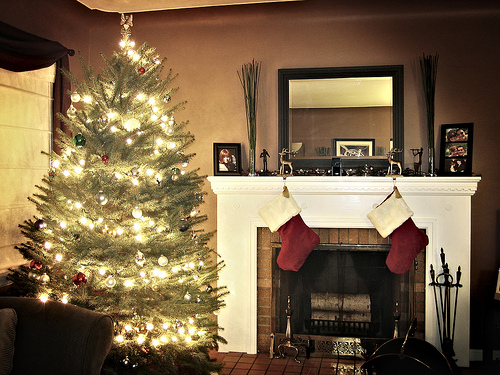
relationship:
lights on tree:
[136, 96, 186, 151] [9, 22, 219, 371]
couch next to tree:
[13, 291, 120, 365] [58, 22, 247, 372]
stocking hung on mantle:
[368, 185, 429, 273] [206, 173, 480, 195]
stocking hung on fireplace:
[258, 189, 320, 272] [260, 226, 493, 355]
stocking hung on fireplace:
[366, 185, 428, 275] [260, 226, 493, 355]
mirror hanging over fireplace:
[280, 72, 400, 160] [260, 217, 427, 344]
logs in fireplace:
[311, 292, 372, 328] [192, 153, 494, 371]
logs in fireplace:
[296, 295, 383, 328] [227, 158, 448, 348]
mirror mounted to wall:
[287, 75, 396, 161] [171, 33, 241, 104]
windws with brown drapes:
[5, 68, 99, 290] [3, 41, 94, 128]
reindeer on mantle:
[276, 150, 297, 173] [202, 140, 494, 196]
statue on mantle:
[255, 145, 272, 175] [205, 171, 483, 201]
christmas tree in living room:
[0, 7, 237, 373] [10, 10, 490, 339]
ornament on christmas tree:
[62, 267, 88, 287] [6, 7, 230, 375]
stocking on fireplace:
[255, 190, 325, 268] [206, 170, 481, 367]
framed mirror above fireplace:
[267, 58, 409, 173] [203, 166, 497, 374]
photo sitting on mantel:
[205, 135, 250, 177] [203, 169, 487, 198]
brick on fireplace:
[212, 349, 338, 374] [257, 226, 424, 359]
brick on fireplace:
[257, 357, 271, 362] [257, 226, 424, 359]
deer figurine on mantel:
[385, 145, 406, 175] [205, 171, 484, 194]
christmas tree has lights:
[6, 7, 230, 375] [64, 87, 171, 248]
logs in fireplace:
[311, 292, 372, 328] [206, 170, 481, 367]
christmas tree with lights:
[6, 7, 230, 375] [51, 153, 170, 195]